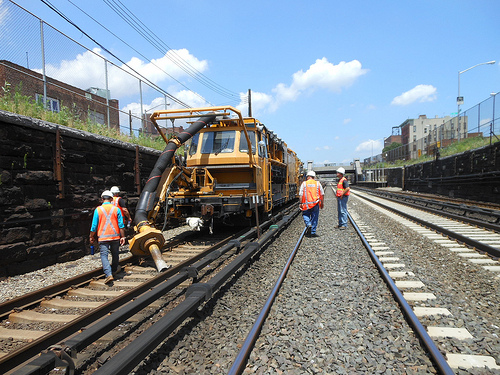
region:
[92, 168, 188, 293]
Construction workers working on the tracks.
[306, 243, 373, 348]
Gravel in between the tracks.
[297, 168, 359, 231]
The men is wearing orange vest.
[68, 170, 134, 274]
the men is wearing hard hats.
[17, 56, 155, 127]
A building above the tracks.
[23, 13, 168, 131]
A wire fence above the tracks.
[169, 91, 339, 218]
A work train on the tracks to repair.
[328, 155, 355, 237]
The man has his hands in his pockets.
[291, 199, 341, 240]
The man is wearing jeans.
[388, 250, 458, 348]
Blocks of concrete in between the tracks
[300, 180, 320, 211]
an orange vest on a man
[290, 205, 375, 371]
gravel along the train tracks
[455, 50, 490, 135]
a light pole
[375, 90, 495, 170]
a chain link fence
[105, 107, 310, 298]
a yellow machine on the tracks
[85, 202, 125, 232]
a blue shirt on a person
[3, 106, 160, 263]
a stone wall next to the tracks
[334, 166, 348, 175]
a white safety helmet no a head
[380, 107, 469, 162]
a concrete building in the distance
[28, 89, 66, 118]
a window in a building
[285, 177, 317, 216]
man wears bright orange shirt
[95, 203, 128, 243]
man wears blue shirt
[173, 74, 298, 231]
train is bright orange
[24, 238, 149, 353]
brown railroad ties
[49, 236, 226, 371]
grey railroad tracks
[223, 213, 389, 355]
grey gravel between track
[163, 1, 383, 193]
sky is blue with few clouds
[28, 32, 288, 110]
clouds are white and puffy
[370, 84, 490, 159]
grey building on hill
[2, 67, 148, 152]
brick building above train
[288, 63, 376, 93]
clouds in the sky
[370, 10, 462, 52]
part of the sky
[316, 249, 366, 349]
gravel on railroad tracks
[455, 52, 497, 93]
a street light on pole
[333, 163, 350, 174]
white construction hat on man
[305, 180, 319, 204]
an orange vest on man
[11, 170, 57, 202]
bricks on the wall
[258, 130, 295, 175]
part of yellow train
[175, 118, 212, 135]
large hose on train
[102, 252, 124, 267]
blue jeans on man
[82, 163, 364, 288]
group of four railroad worker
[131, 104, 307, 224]
yellow and black train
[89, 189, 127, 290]
railroad worker in blue shirt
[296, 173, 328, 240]
railroad worker in white shirt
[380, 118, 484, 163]
brown and white warehouse building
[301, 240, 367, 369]
rock covered ground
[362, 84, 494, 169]
metal chain link fence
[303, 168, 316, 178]
white hard hat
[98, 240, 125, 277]
blue denim jeans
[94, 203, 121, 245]
orange work vest